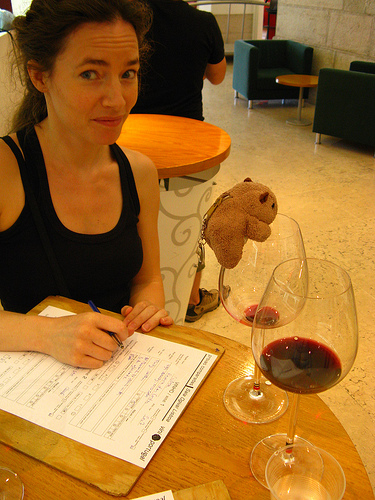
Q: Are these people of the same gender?
A: No, they are both male and female.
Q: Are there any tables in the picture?
A: Yes, there is a table.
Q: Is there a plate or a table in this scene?
A: Yes, there is a table.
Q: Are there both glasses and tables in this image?
A: Yes, there are both a table and glasses.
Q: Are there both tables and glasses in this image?
A: Yes, there are both a table and glasses.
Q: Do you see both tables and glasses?
A: Yes, there are both a table and glasses.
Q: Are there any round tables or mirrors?
A: Yes, there is a round table.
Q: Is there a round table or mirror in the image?
A: Yes, there is a round table.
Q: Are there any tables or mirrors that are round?
A: Yes, the table is round.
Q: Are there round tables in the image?
A: Yes, there is a round table.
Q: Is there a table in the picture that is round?
A: Yes, there is a table that is round.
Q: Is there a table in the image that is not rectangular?
A: Yes, there is a round table.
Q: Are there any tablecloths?
A: No, there are no tablecloths.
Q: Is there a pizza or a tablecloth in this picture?
A: No, there are no tablecloths or pizzas.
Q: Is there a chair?
A: Yes, there is a chair.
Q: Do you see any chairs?
A: Yes, there is a chair.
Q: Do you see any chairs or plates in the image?
A: Yes, there is a chair.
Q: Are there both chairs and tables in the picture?
A: Yes, there are both a chair and a table.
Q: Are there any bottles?
A: No, there are no bottles.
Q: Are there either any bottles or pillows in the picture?
A: No, there are no bottles or pillows.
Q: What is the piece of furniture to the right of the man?
A: The piece of furniture is a chair.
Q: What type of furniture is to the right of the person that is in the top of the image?
A: The piece of furniture is a chair.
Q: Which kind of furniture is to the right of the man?
A: The piece of furniture is a chair.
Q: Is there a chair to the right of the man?
A: Yes, there is a chair to the right of the man.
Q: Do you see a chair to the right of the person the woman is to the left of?
A: Yes, there is a chair to the right of the man.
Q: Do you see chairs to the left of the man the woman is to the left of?
A: No, the chair is to the right of the man.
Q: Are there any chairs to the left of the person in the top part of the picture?
A: No, the chair is to the right of the man.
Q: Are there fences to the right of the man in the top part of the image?
A: No, there is a chair to the right of the man.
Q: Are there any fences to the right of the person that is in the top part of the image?
A: No, there is a chair to the right of the man.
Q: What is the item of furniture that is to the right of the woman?
A: The piece of furniture is a chair.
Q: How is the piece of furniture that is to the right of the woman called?
A: The piece of furniture is a chair.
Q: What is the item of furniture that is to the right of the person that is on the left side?
A: The piece of furniture is a chair.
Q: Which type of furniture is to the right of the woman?
A: The piece of furniture is a chair.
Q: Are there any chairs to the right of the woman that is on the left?
A: Yes, there is a chair to the right of the woman.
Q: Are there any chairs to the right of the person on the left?
A: Yes, there is a chair to the right of the woman.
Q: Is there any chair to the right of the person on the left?
A: Yes, there is a chair to the right of the woman.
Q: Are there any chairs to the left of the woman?
A: No, the chair is to the right of the woman.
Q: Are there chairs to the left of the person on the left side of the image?
A: No, the chair is to the right of the woman.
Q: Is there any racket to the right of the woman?
A: No, there is a chair to the right of the woman.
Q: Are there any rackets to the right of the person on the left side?
A: No, there is a chair to the right of the woman.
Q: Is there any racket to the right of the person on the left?
A: No, there is a chair to the right of the woman.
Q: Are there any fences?
A: No, there are no fences.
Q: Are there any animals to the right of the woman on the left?
A: Yes, there is an animal to the right of the woman.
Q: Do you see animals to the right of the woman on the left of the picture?
A: Yes, there is an animal to the right of the woman.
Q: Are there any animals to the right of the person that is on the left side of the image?
A: Yes, there is an animal to the right of the woman.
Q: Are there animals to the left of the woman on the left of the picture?
A: No, the animal is to the right of the woman.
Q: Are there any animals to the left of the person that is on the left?
A: No, the animal is to the right of the woman.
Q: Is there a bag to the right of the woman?
A: No, there is an animal to the right of the woman.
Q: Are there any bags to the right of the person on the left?
A: No, there is an animal to the right of the woman.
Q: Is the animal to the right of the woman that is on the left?
A: Yes, the animal is to the right of the woman.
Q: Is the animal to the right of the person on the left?
A: Yes, the animal is to the right of the woman.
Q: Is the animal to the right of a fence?
A: No, the animal is to the right of the woman.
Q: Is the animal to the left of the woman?
A: No, the animal is to the right of the woman.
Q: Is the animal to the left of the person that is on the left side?
A: No, the animal is to the right of the woman.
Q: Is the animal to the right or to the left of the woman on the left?
A: The animal is to the right of the woman.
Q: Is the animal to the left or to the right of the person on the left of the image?
A: The animal is to the right of the woman.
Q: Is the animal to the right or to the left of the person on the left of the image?
A: The animal is to the right of the woman.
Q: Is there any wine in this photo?
A: Yes, there is wine.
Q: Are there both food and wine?
A: No, there is wine but no food.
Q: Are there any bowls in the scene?
A: No, there are no bowls.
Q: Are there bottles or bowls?
A: No, there are no bowls or bottles.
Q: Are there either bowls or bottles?
A: No, there are no bowls or bottles.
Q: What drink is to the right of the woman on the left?
A: The drink is wine.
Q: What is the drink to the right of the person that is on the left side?
A: The drink is wine.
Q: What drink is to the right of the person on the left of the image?
A: The drink is wine.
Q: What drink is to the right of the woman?
A: The drink is wine.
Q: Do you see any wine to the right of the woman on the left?
A: Yes, there is wine to the right of the woman.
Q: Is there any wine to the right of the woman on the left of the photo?
A: Yes, there is wine to the right of the woman.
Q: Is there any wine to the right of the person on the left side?
A: Yes, there is wine to the right of the woman.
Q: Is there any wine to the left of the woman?
A: No, the wine is to the right of the woman.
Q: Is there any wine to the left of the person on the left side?
A: No, the wine is to the right of the woman.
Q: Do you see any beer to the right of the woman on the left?
A: No, there is wine to the right of the woman.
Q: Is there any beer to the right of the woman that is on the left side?
A: No, there is wine to the right of the woman.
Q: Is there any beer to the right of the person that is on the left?
A: No, there is wine to the right of the woman.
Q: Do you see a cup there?
A: Yes, there is a cup.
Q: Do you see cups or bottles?
A: Yes, there is a cup.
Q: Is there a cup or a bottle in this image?
A: Yes, there is a cup.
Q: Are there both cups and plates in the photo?
A: No, there is a cup but no plates.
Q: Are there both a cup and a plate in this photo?
A: No, there is a cup but no plates.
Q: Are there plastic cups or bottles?
A: Yes, there is a plastic cup.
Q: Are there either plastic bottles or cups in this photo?
A: Yes, there is a plastic cup.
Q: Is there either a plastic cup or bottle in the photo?
A: Yes, there is a plastic cup.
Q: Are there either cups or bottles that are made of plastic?
A: Yes, the cup is made of plastic.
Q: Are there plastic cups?
A: Yes, there is a cup that is made of plastic.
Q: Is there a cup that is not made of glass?
A: Yes, there is a cup that is made of plastic.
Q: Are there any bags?
A: No, there are no bags.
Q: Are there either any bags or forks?
A: No, there are no bags or forks.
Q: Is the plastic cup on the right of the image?
A: Yes, the cup is on the right of the image.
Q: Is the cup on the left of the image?
A: No, the cup is on the right of the image.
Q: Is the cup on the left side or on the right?
A: The cup is on the right of the image.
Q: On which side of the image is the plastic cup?
A: The cup is on the right of the image.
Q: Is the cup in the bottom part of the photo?
A: Yes, the cup is in the bottom of the image.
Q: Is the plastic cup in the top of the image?
A: No, the cup is in the bottom of the image.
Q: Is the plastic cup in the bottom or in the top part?
A: The cup is in the bottom of the image.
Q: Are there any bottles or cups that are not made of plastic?
A: No, there is a cup but it is made of plastic.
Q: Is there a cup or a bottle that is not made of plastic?
A: No, there is a cup but it is made of plastic.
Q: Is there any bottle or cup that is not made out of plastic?
A: No, there is a cup but it is made of plastic.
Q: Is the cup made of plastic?
A: Yes, the cup is made of plastic.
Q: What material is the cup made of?
A: The cup is made of plastic.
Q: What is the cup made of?
A: The cup is made of plastic.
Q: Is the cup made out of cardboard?
A: No, the cup is made of plastic.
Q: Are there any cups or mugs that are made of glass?
A: No, there is a cup but it is made of plastic.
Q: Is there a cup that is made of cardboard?
A: No, there is a cup but it is made of plastic.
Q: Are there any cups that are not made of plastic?
A: No, there is a cup but it is made of plastic.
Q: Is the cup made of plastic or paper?
A: The cup is made of plastic.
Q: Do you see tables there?
A: Yes, there is a table.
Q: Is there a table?
A: Yes, there is a table.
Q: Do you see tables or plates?
A: Yes, there is a table.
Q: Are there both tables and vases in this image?
A: No, there is a table but no vases.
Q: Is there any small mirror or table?
A: Yes, there is a small table.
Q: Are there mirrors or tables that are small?
A: Yes, the table is small.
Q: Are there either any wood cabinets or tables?
A: Yes, there is a wood table.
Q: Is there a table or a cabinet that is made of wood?
A: Yes, the table is made of wood.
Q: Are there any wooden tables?
A: Yes, there is a wood table.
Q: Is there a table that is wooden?
A: Yes, there is a table that is wooden.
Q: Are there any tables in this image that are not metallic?
A: Yes, there is a wooden table.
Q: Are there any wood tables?
A: Yes, there is a table that is made of wood.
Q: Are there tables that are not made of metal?
A: Yes, there is a table that is made of wood.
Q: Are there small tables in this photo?
A: Yes, there is a small table.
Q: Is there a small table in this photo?
A: Yes, there is a small table.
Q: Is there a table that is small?
A: Yes, there is a table that is small.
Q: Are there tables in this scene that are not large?
A: Yes, there is a small table.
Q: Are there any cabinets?
A: No, there are no cabinets.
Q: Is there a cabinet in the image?
A: No, there are no cabinets.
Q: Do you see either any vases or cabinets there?
A: No, there are no cabinets or vases.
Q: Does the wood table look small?
A: Yes, the table is small.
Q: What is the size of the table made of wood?
A: The table is small.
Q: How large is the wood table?
A: The table is small.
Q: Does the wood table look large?
A: No, the table is small.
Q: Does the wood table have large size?
A: No, the table is small.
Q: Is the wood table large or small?
A: The table is small.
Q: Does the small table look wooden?
A: Yes, the table is wooden.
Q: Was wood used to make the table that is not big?
A: Yes, the table is made of wood.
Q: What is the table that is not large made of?
A: The table is made of wood.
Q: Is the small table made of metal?
A: No, the table is made of wood.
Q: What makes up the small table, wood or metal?
A: The table is made of wood.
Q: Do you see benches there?
A: No, there are no benches.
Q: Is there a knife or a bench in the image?
A: No, there are no benches or knives.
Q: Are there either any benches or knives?
A: No, there are no benches or knives.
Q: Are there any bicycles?
A: No, there are no bicycles.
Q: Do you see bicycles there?
A: No, there are no bicycles.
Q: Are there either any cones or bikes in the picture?
A: No, there are no bikes or cones.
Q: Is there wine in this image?
A: Yes, there is wine.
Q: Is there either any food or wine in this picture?
A: Yes, there is wine.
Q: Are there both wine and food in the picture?
A: No, there is wine but no food.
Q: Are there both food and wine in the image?
A: No, there is wine but no food.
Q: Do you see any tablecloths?
A: No, there are no tablecloths.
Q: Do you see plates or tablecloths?
A: No, there are no tablecloths or plates.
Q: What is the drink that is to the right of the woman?
A: The drink is wine.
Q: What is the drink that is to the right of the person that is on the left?
A: The drink is wine.